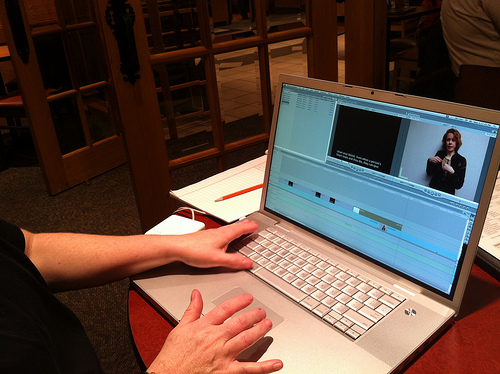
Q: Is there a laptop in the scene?
A: Yes, there is a laptop.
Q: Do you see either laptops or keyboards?
A: Yes, there is a laptop.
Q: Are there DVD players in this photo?
A: No, there are no DVD players.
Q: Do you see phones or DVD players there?
A: No, there are no DVD players or phones.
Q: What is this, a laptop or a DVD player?
A: This is a laptop.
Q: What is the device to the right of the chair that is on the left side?
A: The device is a laptop.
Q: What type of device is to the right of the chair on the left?
A: The device is a laptop.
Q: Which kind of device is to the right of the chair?
A: The device is a laptop.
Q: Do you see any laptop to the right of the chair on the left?
A: Yes, there is a laptop to the right of the chair.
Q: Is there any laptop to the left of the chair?
A: No, the laptop is to the right of the chair.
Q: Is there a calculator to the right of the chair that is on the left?
A: No, there is a laptop to the right of the chair.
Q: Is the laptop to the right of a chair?
A: Yes, the laptop is to the right of a chair.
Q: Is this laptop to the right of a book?
A: No, the laptop is to the right of a chair.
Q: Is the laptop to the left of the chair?
A: No, the laptop is to the right of the chair.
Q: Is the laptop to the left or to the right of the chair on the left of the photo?
A: The laptop is to the right of the chair.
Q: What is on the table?
A: The laptop is on the table.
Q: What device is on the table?
A: The device is a laptop.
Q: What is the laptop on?
A: The laptop is on the table.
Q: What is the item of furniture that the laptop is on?
A: The piece of furniture is a table.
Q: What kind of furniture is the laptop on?
A: The laptop is on the table.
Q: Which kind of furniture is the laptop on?
A: The laptop is on the table.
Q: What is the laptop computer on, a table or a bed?
A: The laptop computer is on a table.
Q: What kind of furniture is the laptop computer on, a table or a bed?
A: The laptop computer is on a table.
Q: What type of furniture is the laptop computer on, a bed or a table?
A: The laptop computer is on a table.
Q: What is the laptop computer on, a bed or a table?
A: The laptop computer is on a table.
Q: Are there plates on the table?
A: No, there is a laptop on the table.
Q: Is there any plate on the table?
A: No, there is a laptop on the table.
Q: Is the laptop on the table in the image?
A: Yes, the laptop is on the table.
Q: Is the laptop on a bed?
A: No, the laptop is on the table.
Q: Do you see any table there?
A: Yes, there is a table.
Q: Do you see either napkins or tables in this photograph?
A: Yes, there is a table.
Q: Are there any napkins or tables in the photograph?
A: Yes, there is a table.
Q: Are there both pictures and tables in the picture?
A: No, there is a table but no pictures.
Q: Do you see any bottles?
A: No, there are no bottles.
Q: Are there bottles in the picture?
A: No, there are no bottles.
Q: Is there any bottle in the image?
A: No, there are no bottles.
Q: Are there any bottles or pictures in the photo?
A: No, there are no bottles or pictures.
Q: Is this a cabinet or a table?
A: This is a table.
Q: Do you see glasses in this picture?
A: No, there are no glasses.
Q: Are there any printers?
A: No, there are no printers.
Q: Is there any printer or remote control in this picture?
A: No, there are no printers or remote controls.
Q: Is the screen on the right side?
A: Yes, the screen is on the right of the image.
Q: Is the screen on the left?
A: No, the screen is on the right of the image.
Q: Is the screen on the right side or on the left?
A: The screen is on the right of the image.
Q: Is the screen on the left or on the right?
A: The screen is on the right of the image.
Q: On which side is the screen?
A: The screen is on the right of the image.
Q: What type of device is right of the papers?
A: The device is a screen.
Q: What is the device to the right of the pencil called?
A: The device is a screen.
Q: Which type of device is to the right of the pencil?
A: The device is a screen.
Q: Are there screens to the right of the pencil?
A: Yes, there is a screen to the right of the pencil.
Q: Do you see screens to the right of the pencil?
A: Yes, there is a screen to the right of the pencil.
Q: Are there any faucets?
A: No, there are no faucets.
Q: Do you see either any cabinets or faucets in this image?
A: No, there are no faucets or cabinets.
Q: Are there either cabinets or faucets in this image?
A: No, there are no faucets or cabinets.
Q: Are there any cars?
A: No, there are no cars.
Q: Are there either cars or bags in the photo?
A: No, there are no cars or bags.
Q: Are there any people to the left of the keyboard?
A: Yes, there is a person to the left of the keyboard.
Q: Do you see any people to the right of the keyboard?
A: No, the person is to the left of the keyboard.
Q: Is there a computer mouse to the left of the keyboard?
A: No, there is a person to the left of the keyboard.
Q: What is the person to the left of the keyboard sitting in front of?
A: The person is sitting in front of the laptop.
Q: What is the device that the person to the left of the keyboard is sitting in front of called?
A: The device is a laptop.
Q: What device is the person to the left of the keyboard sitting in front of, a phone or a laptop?
A: The person is sitting in front of a laptop.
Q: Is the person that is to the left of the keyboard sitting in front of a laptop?
A: Yes, the person is sitting in front of a laptop.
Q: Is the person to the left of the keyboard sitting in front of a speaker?
A: No, the person is sitting in front of a laptop.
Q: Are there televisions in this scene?
A: No, there are no televisions.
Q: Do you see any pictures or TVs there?
A: No, there are no TVs or pictures.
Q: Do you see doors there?
A: Yes, there is a door.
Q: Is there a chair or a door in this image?
A: Yes, there is a door.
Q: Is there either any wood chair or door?
A: Yes, there is a wood door.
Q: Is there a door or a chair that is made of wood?
A: Yes, the door is made of wood.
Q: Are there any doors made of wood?
A: Yes, there is a door that is made of wood.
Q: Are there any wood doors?
A: Yes, there is a door that is made of wood.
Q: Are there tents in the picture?
A: No, there are no tents.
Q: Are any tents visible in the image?
A: No, there are no tents.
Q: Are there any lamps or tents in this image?
A: No, there are no tents or lamps.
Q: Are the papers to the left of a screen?
A: Yes, the papers are to the left of a screen.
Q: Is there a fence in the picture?
A: No, there are no fences.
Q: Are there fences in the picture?
A: No, there are no fences.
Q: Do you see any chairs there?
A: Yes, there is a chair.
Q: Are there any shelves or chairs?
A: Yes, there is a chair.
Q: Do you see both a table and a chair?
A: Yes, there are both a chair and a table.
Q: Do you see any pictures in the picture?
A: No, there are no pictures.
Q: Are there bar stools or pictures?
A: No, there are no pictures or bar stools.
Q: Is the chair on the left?
A: Yes, the chair is on the left of the image.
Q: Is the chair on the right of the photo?
A: No, the chair is on the left of the image.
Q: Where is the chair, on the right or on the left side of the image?
A: The chair is on the left of the image.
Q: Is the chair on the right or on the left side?
A: The chair is on the left of the image.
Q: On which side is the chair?
A: The chair is on the left of the image.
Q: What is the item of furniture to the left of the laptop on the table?
A: The piece of furniture is a chair.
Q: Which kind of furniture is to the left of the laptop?
A: The piece of furniture is a chair.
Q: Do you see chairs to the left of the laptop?
A: Yes, there is a chair to the left of the laptop.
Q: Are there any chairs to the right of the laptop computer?
A: No, the chair is to the left of the laptop computer.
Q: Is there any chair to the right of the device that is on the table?
A: No, the chair is to the left of the laptop computer.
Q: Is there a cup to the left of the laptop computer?
A: No, there is a chair to the left of the laptop computer.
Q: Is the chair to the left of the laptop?
A: Yes, the chair is to the left of the laptop.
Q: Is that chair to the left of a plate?
A: No, the chair is to the left of the laptop.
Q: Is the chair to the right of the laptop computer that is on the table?
A: No, the chair is to the left of the laptop.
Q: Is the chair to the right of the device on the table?
A: No, the chair is to the left of the laptop.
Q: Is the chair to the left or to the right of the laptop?
A: The chair is to the left of the laptop.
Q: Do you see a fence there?
A: No, there are no fences.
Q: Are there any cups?
A: No, there are no cups.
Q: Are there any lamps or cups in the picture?
A: No, there are no cups or lamps.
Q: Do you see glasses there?
A: No, there are no glasses.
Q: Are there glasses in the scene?
A: No, there are no glasses.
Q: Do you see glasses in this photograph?
A: No, there are no glasses.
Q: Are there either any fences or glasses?
A: No, there are no glasses or fences.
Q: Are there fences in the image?
A: No, there are no fences.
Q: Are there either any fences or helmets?
A: No, there are no fences or helmets.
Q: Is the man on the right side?
A: Yes, the man is on the right of the image.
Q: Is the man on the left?
A: No, the man is on the right of the image.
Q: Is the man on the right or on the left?
A: The man is on the right of the image.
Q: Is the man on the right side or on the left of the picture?
A: The man is on the right of the image.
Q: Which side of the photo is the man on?
A: The man is on the right of the image.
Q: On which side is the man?
A: The man is on the right of the image.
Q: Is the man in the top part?
A: Yes, the man is in the top of the image.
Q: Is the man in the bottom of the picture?
A: No, the man is in the top of the image.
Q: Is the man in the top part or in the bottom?
A: The man is in the top of the image.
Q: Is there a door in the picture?
A: Yes, there is a door.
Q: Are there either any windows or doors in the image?
A: Yes, there is a door.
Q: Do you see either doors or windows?
A: Yes, there is a door.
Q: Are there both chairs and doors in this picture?
A: Yes, there are both a door and a chair.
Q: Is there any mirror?
A: No, there are no mirrors.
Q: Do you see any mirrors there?
A: No, there are no mirrors.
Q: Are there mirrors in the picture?
A: No, there are no mirrors.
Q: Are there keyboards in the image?
A: Yes, there is a keyboard.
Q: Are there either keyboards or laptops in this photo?
A: Yes, there is a keyboard.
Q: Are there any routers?
A: No, there are no routers.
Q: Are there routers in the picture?
A: No, there are no routers.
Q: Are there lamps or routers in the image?
A: No, there are no routers or lamps.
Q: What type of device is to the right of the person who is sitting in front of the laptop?
A: The device is a keyboard.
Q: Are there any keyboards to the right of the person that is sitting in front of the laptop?
A: Yes, there is a keyboard to the right of the person.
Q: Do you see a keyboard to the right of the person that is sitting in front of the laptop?
A: Yes, there is a keyboard to the right of the person.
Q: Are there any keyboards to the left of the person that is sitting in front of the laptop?
A: No, the keyboard is to the right of the person.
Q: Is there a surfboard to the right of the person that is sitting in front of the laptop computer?
A: No, there is a keyboard to the right of the person.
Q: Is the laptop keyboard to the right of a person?
A: Yes, the keyboard is to the right of a person.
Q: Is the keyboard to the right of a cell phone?
A: No, the keyboard is to the right of a person.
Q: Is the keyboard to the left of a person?
A: No, the keyboard is to the right of a person.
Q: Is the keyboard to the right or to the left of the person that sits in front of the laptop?
A: The keyboard is to the right of the person.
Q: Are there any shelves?
A: No, there are no shelves.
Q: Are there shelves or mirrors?
A: No, there are no shelves or mirrors.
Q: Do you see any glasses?
A: No, there are no glasses.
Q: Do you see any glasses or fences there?
A: No, there are no glasses or fences.